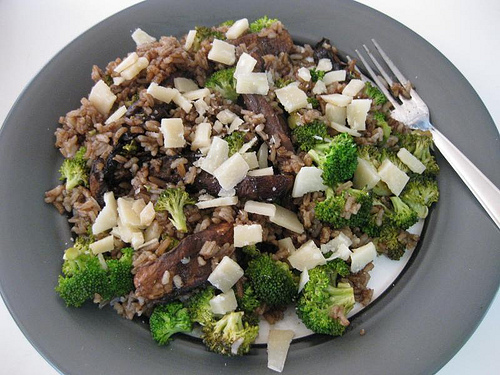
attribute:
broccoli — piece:
[286, 119, 410, 228]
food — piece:
[64, 33, 417, 352]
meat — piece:
[140, 246, 220, 294]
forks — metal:
[340, 37, 484, 217]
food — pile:
[65, 51, 422, 333]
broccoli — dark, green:
[293, 255, 365, 341]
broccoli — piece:
[313, 255, 397, 349]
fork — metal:
[327, 13, 483, 216]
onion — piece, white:
[268, 330, 279, 372]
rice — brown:
[116, 288, 144, 316]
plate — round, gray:
[18, 8, 483, 333]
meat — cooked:
[139, 242, 222, 320]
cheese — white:
[161, 112, 191, 154]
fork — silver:
[342, 32, 484, 231]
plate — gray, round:
[2, 2, 471, 370]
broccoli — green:
[232, 251, 307, 322]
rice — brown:
[145, 41, 199, 79]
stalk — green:
[328, 279, 360, 309]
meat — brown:
[122, 219, 249, 305]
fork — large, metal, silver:
[336, 29, 484, 206]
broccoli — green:
[46, 231, 139, 320]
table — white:
[1, 3, 483, 372]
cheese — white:
[213, 150, 255, 190]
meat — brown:
[131, 260, 185, 308]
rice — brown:
[147, 179, 246, 249]